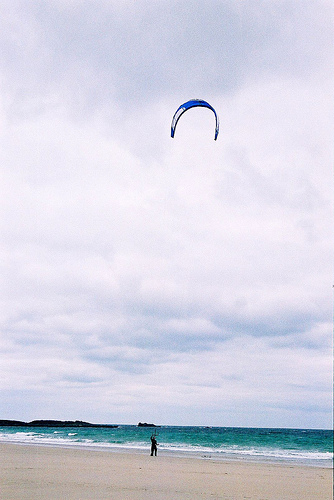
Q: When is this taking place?
A: Daytime.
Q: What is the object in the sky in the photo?
A: Kite.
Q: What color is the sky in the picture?
A: Blue.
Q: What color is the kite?
A: Blue.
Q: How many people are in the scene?
A: One.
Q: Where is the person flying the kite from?
A: Sand.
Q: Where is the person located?
A: Beach.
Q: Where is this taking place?
A: At a quiet beach near the ocean.